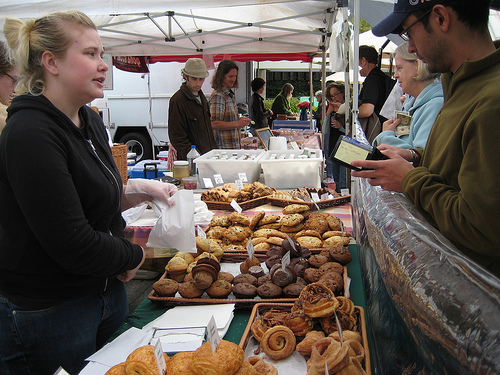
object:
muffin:
[152, 278, 179, 297]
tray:
[147, 252, 350, 305]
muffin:
[165, 257, 188, 283]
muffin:
[174, 252, 195, 265]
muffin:
[178, 281, 205, 299]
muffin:
[191, 263, 218, 289]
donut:
[260, 325, 296, 361]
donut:
[306, 336, 352, 373]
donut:
[281, 310, 313, 337]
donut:
[303, 292, 339, 318]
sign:
[101, 53, 114, 90]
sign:
[203, 178, 214, 188]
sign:
[213, 174, 224, 185]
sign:
[238, 172, 248, 182]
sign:
[235, 180, 244, 192]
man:
[350, 0, 500, 280]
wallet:
[329, 135, 391, 180]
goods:
[207, 152, 256, 161]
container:
[193, 149, 267, 189]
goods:
[269, 147, 317, 160]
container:
[258, 149, 324, 189]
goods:
[184, 182, 197, 190]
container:
[182, 177, 198, 190]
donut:
[250, 313, 287, 342]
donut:
[335, 296, 354, 315]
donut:
[299, 282, 335, 305]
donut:
[319, 310, 357, 335]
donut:
[327, 330, 361, 343]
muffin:
[232, 283, 258, 300]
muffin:
[257, 282, 283, 299]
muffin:
[248, 265, 267, 277]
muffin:
[257, 274, 272, 285]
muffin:
[271, 264, 298, 289]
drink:
[187, 145, 201, 177]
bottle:
[186, 145, 201, 174]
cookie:
[222, 226, 247, 243]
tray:
[197, 221, 348, 254]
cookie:
[222, 244, 247, 251]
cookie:
[227, 211, 250, 226]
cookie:
[206, 226, 227, 240]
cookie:
[210, 215, 231, 228]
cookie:
[249, 211, 265, 230]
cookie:
[259, 213, 282, 225]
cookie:
[259, 222, 281, 230]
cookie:
[253, 228, 288, 238]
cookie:
[251, 237, 267, 246]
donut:
[296, 330, 326, 356]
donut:
[344, 340, 365, 363]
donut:
[335, 356, 367, 375]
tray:
[237, 302, 371, 375]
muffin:
[240, 257, 261, 275]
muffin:
[217, 271, 234, 282]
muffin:
[206, 280, 232, 300]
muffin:
[266, 247, 283, 259]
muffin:
[265, 255, 282, 270]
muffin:
[282, 239, 302, 258]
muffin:
[301, 246, 312, 260]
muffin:
[289, 257, 309, 276]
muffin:
[283, 282, 307, 297]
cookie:
[281, 204, 310, 215]